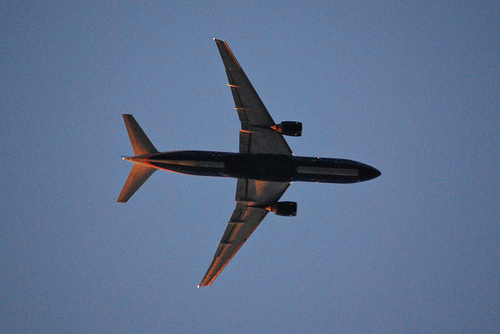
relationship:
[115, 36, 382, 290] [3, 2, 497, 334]
airplane in sky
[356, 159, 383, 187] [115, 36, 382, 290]
nose of airplane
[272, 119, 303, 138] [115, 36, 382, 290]
engine on airplane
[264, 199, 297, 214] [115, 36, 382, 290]
engine on airplane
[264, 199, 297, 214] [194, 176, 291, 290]
engine on left wing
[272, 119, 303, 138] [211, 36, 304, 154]
engine on right wing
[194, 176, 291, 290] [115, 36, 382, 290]
left wing on airplane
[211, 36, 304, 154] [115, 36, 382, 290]
right wing on airplane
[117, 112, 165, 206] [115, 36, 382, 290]
tail on airplane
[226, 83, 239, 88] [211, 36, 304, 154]
aileron under right wing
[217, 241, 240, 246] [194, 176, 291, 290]
aileron under left wing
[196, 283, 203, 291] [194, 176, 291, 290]
light on end of left wing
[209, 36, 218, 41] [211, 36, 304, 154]
light on end of right wing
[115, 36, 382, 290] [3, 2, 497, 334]
airplane against sky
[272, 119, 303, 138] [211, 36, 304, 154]
engine attached to right wing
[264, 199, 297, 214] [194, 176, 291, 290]
engine attached to left wing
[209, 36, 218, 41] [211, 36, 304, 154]
light on tip of right wing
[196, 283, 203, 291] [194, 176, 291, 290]
light on tip of left wing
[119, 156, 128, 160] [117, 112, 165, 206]
light on tip of tail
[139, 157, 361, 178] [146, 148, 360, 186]
line on body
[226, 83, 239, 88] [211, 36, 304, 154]
aileron are across right wing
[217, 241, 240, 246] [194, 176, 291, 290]
aileron are across left wing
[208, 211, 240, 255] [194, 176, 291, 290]
aileron on left wing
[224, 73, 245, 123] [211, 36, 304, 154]
aileron on right wing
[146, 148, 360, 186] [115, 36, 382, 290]
body of airplane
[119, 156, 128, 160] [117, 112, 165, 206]
light on tail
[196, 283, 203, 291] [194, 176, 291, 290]
light on left wing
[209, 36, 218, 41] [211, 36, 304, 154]
light on right wing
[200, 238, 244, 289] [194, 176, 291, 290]
reflection on left wing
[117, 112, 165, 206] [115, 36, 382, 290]
tail of airplane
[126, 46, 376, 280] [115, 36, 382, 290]
underside of airplane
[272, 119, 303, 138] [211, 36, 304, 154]
engine sticks out from right wing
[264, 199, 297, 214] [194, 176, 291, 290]
engine sticks out from left wing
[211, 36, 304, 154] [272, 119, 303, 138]
right wing holds engine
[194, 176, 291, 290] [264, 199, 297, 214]
left wing holds engine